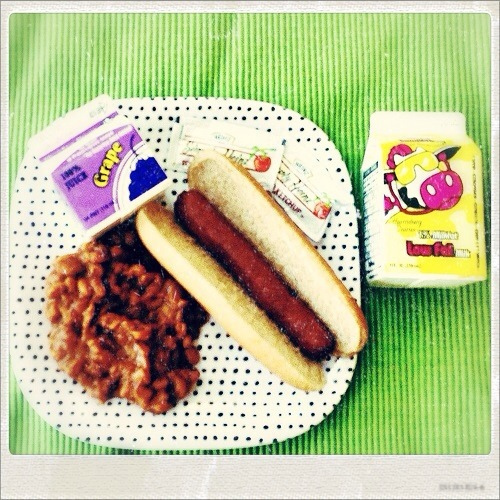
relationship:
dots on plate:
[209, 366, 264, 431] [6, 94, 361, 451]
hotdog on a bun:
[172, 186, 335, 361] [123, 153, 373, 388]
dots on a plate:
[218, 413, 221, 418] [6, 94, 361, 451]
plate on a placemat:
[6, 94, 361, 451] [7, 13, 492, 456]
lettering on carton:
[407, 239, 455, 258] [360, 111, 488, 289]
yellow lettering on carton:
[86, 139, 127, 187] [28, 93, 175, 242]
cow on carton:
[377, 140, 462, 217] [360, 111, 488, 289]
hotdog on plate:
[137, 152, 372, 393] [6, 94, 361, 451]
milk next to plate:
[366, 109, 498, 282] [6, 94, 361, 451]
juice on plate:
[36, 90, 172, 230] [44, 78, 371, 443]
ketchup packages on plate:
[170, 126, 331, 247] [6, 94, 361, 451]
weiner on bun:
[184, 208, 326, 346] [253, 179, 352, 281]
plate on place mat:
[6, 94, 361, 451] [8, 12, 492, 452]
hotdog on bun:
[137, 152, 372, 393] [142, 153, 366, 388]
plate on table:
[6, 94, 361, 451] [7, 14, 491, 451]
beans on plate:
[39, 238, 203, 414] [6, 94, 361, 451]